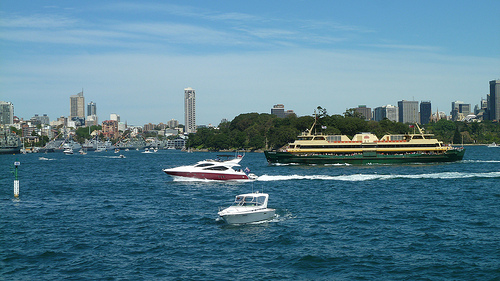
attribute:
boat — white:
[204, 178, 285, 240]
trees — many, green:
[186, 112, 313, 151]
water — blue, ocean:
[68, 154, 470, 276]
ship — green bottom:
[264, 123, 465, 165]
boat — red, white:
[157, 152, 249, 191]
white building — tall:
[181, 87, 198, 137]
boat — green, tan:
[263, 112, 474, 172]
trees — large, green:
[199, 110, 291, 143]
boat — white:
[222, 191, 281, 221]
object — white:
[7, 153, 31, 203]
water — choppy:
[345, 206, 495, 245]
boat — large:
[254, 126, 466, 178]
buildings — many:
[338, 77, 498, 127]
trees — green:
[186, 108, 498, 149]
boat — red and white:
[162, 150, 256, 182]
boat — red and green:
[260, 124, 467, 164]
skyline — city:
[1, 84, 483, 118]